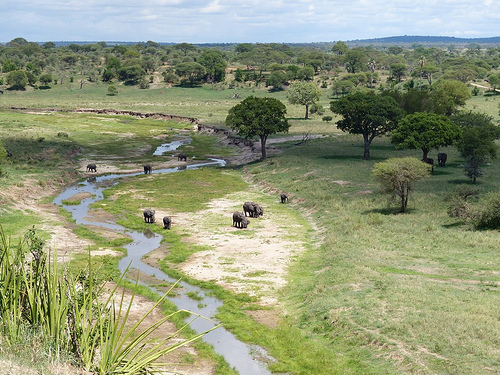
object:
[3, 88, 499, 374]
ground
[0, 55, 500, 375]
field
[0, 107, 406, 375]
nappier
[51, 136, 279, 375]
river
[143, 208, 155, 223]
elephant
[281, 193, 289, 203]
elephant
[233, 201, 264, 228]
elephants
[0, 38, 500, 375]
savannah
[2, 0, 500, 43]
sky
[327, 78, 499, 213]
trees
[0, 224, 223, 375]
leaves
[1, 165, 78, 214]
rim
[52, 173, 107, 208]
water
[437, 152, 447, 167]
elephant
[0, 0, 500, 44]
clouds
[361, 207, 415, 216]
shadow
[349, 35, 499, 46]
mountain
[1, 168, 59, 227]
ridge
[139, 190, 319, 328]
patch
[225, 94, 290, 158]
trees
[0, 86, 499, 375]
grass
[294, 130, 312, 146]
branch